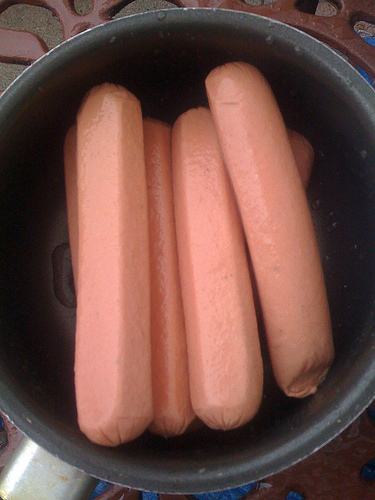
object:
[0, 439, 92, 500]
handle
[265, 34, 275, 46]
drops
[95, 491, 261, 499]
flame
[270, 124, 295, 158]
ground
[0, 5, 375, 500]
pan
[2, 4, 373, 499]
photo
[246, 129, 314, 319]
hot dogs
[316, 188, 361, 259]
water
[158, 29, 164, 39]
water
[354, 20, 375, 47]
plastichole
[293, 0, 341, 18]
plastichole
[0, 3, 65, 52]
plastichole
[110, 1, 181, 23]
plastichole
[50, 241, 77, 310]
water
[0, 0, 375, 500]
stove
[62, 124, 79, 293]
hotdog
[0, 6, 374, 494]
black pot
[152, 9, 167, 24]
droplet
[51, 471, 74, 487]
brown mark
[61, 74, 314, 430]
pile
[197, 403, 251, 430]
lines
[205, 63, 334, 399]
hot dog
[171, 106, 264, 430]
hot dog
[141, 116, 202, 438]
hot dog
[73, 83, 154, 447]
hot dog